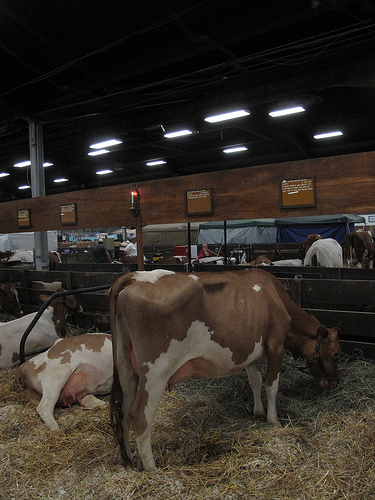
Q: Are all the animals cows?
A: Yes, all the animals are cows.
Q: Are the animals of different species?
A: No, all the animals are cows.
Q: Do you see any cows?
A: Yes, there is a cow.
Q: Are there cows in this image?
A: Yes, there is a cow.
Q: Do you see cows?
A: Yes, there is a cow.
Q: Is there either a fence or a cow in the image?
A: Yes, there is a cow.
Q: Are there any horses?
A: No, there are no horses.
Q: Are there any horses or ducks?
A: No, there are no horses or ducks.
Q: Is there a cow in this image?
A: Yes, there is a cow.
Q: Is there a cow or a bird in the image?
A: Yes, there is a cow.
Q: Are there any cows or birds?
A: Yes, there is a cow.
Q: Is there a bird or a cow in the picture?
A: Yes, there is a cow.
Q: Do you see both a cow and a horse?
A: No, there is a cow but no horses.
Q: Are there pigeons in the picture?
A: No, there are no pigeons.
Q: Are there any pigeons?
A: No, there are no pigeons.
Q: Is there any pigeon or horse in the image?
A: No, there are no pigeons or horses.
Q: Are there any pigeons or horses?
A: No, there are no pigeons or horses.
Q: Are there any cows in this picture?
A: Yes, there is a cow.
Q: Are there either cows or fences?
A: Yes, there is a cow.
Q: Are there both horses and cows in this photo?
A: No, there is a cow but no horses.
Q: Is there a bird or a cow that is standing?
A: Yes, the cow is standing.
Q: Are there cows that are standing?
A: Yes, there is a cow that is standing.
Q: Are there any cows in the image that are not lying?
A: Yes, there is a cow that is standing.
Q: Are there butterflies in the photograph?
A: No, there are no butterflies.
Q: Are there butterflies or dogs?
A: No, there are no butterflies or dogs.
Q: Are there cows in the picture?
A: Yes, there is a cow.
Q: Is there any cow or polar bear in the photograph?
A: Yes, there is a cow.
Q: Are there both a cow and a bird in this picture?
A: No, there is a cow but no birds.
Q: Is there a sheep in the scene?
A: No, there is no sheep.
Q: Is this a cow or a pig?
A: This is a cow.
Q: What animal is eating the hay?
A: The cow is eating the hay.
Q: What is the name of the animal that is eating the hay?
A: The animal is a cow.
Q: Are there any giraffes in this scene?
A: No, there are no giraffes.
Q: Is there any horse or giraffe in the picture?
A: No, there are no giraffes or horses.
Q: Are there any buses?
A: No, there are no buses.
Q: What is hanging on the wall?
A: The sign is hanging on the wall.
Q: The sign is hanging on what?
A: The sign is hanging on the wall.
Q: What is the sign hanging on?
A: The sign is hanging on the wall.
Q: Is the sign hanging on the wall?
A: Yes, the sign is hanging on the wall.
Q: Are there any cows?
A: Yes, there is a cow.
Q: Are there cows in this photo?
A: Yes, there is a cow.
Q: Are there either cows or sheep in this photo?
A: Yes, there is a cow.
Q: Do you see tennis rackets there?
A: No, there are no tennis rackets.